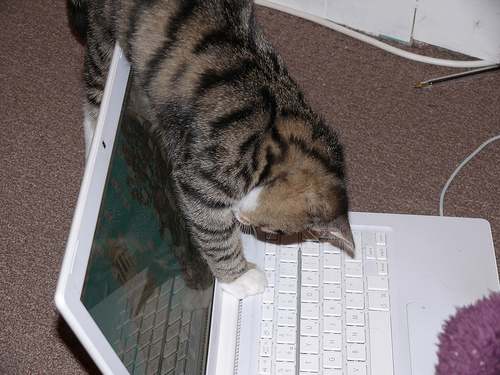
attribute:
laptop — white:
[76, 111, 496, 341]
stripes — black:
[132, 0, 263, 127]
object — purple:
[434, 290, 499, 374]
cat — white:
[109, 19, 427, 339]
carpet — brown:
[355, 100, 430, 190]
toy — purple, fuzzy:
[425, 284, 495, 374]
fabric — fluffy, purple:
[437, 291, 499, 374]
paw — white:
[218, 263, 268, 303]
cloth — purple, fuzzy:
[435, 290, 496, 370]